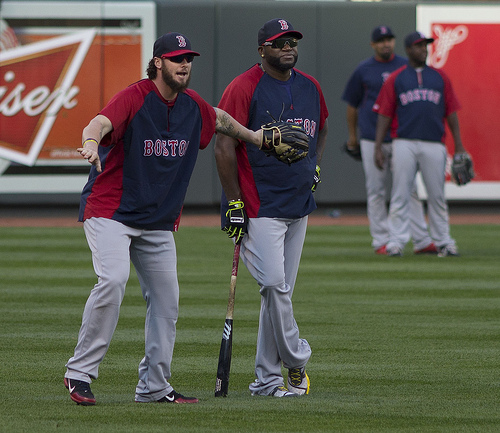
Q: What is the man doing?
A: Waiting to catch the ball.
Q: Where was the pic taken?
A: In the field.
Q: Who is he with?
A: Other players.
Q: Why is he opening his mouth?
A: He is talking.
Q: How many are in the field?
A: 4.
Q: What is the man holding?
A: A bat.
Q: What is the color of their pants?
A: Gray.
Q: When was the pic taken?
A: During the day.